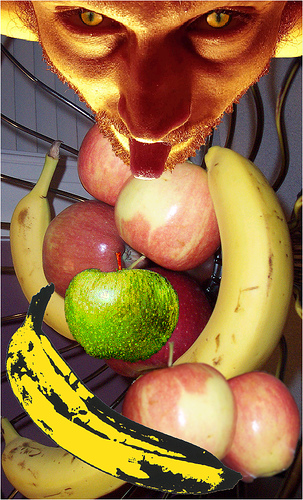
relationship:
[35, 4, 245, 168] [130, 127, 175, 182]
man has tongue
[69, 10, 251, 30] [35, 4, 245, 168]
eyes on man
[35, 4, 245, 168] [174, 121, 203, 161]
man has stubble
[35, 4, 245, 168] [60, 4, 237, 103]
man has face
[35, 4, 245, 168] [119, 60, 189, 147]
man has nose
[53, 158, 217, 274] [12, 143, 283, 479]
apples in group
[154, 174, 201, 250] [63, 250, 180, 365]
abrasions on fruit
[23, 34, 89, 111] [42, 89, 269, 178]
side of beard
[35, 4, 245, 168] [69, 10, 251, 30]
person has eyes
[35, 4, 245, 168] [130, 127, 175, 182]
person has tongue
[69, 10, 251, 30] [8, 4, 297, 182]
eyes on man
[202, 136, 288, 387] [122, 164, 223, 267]
banana by apple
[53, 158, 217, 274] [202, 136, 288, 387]
apples behind banana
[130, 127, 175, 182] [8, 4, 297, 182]
tongue of man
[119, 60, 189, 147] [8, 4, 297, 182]
nose of man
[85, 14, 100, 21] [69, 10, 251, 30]
pupil of eyes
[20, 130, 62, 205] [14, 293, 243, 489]
stem of banana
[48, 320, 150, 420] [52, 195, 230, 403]
stand for fruit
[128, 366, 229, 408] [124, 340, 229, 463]
top of apple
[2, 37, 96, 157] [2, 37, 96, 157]
panels on panels